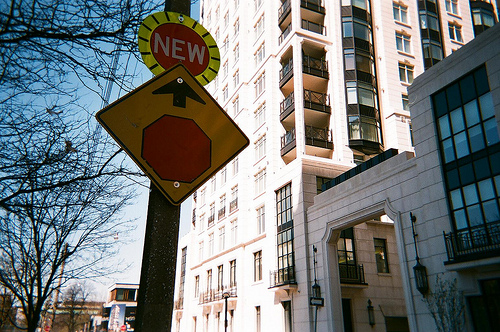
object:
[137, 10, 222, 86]
sign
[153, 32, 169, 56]
lettering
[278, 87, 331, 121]
balcony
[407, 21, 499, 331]
building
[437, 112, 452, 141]
window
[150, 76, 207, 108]
arrow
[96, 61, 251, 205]
sign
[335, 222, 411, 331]
wall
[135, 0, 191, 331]
pole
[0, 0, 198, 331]
trees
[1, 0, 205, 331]
no leaves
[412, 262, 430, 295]
light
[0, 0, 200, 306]
sky